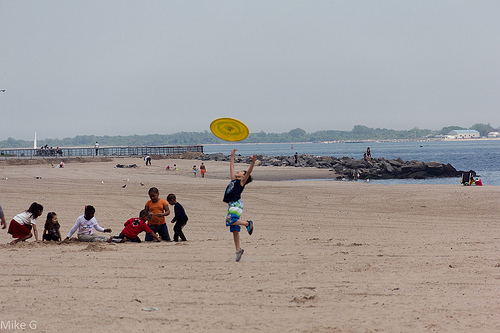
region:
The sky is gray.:
[161, 17, 412, 100]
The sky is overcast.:
[136, 10, 355, 91]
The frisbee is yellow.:
[203, 105, 253, 156]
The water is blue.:
[451, 147, 497, 160]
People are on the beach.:
[11, 185, 201, 263]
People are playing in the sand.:
[3, 178, 194, 268]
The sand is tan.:
[298, 240, 473, 315]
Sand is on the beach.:
[336, 256, 486, 324]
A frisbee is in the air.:
[198, 97, 260, 149]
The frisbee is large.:
[192, 91, 277, 146]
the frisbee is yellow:
[190, 105, 257, 147]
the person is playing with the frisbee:
[181, 91, 273, 277]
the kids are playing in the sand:
[2, 181, 199, 250]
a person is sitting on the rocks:
[327, 133, 444, 183]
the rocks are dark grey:
[336, 149, 467, 180]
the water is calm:
[270, 140, 481, 167]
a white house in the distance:
[421, 120, 494, 152]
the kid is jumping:
[175, 101, 280, 264]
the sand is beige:
[282, 199, 460, 304]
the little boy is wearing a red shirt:
[109, 204, 161, 249]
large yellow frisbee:
[204, 111, 259, 147]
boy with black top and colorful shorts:
[218, 151, 258, 262]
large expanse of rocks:
[188, 142, 469, 179]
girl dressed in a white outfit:
[77, 198, 109, 250]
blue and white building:
[445, 124, 483, 141]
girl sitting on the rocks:
[359, 145, 375, 162]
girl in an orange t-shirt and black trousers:
[143, 184, 170, 241]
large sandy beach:
[17, 162, 462, 310]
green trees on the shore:
[25, 123, 429, 144]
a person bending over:
[142, 153, 158, 165]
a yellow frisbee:
[206, 114, 247, 144]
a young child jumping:
[222, 148, 260, 262]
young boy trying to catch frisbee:
[208, 114, 265, 267]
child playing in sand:
[63, 202, 112, 244]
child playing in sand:
[40, 211, 62, 240]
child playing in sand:
[11, 199, 41, 242]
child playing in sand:
[116, 214, 151, 241]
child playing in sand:
[163, 194, 190, 244]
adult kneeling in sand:
[137, 186, 172, 244]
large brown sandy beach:
[2, 154, 497, 327]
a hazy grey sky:
[6, 4, 498, 141]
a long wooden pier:
[5, 143, 202, 157]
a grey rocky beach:
[245, 145, 463, 182]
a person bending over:
[140, 154, 151, 165]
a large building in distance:
[446, 127, 481, 139]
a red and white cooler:
[471, 176, 482, 184]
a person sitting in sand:
[58, 161, 65, 169]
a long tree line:
[0, 119, 498, 146]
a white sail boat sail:
[29, 130, 39, 150]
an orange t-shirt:
[140, 196, 170, 228]